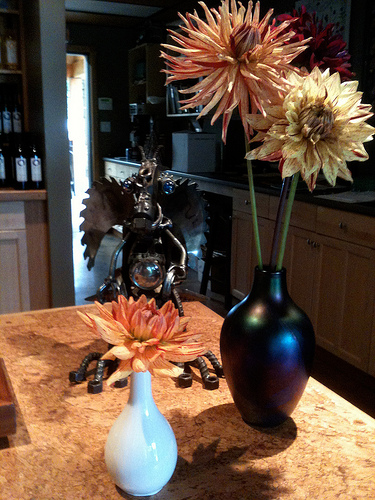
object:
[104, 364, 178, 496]
flower vase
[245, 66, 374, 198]
flower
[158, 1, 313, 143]
flower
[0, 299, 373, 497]
table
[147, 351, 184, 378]
petal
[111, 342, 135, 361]
petal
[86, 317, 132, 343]
petal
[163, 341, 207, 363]
petal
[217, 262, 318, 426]
vase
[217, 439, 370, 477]
granite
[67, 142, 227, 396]
decoration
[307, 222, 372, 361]
cabinets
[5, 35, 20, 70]
bottles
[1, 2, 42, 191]
shelves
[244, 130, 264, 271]
stems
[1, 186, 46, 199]
table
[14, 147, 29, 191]
bottles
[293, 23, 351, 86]
flower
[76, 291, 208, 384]
flower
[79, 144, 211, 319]
statue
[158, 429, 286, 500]
shadow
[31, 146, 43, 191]
bottles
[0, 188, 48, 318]
shelf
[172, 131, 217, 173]
box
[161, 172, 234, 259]
counter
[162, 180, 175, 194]
lights